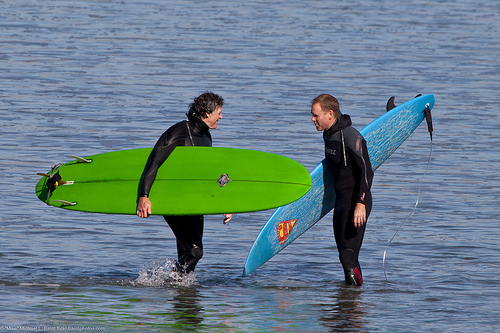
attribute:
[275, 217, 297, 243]
design — red, yellow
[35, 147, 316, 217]
green surfboard — bright green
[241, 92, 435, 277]
surfboard — blue 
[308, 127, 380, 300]
wet suit — black 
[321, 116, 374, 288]
man — wearing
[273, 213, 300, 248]
superman symbol — red, yellow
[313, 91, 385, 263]
man — holding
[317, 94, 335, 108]
hair — short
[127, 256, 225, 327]
water — splashing up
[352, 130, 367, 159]
markings — red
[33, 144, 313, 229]
surfboard — green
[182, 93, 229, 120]
hair — black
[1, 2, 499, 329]
water body — large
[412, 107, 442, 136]
fins — black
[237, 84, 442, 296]
surfboard — blue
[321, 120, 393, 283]
wetsuit — black